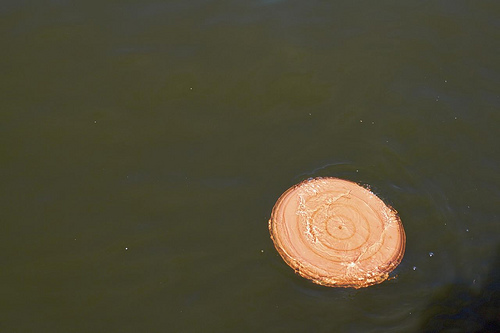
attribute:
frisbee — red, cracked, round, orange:
[270, 176, 405, 286]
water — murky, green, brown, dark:
[1, 1, 498, 331]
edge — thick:
[268, 213, 340, 289]